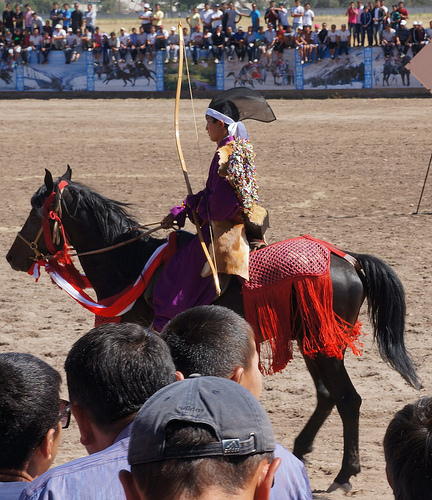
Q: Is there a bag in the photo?
A: No, there are no bags.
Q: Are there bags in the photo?
A: No, there are no bags.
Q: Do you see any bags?
A: No, there are no bags.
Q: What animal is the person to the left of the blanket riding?
A: The person is riding a horse.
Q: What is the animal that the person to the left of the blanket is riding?
A: The animal is a horse.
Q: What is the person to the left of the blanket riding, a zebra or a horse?
A: The person is riding a horse.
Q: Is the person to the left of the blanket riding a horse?
A: Yes, the person is riding a horse.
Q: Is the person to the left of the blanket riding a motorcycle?
A: No, the person is riding a horse.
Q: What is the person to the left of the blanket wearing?
A: The person is wearing a dress.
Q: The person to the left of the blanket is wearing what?
A: The person is wearing a dress.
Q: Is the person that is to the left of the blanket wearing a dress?
A: Yes, the person is wearing a dress.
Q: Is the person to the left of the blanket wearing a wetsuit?
A: No, the person is wearing a dress.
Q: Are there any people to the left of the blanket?
A: Yes, there is a person to the left of the blanket.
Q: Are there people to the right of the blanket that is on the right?
A: No, the person is to the left of the blanket.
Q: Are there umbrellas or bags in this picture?
A: No, there are no bags or umbrellas.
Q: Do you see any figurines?
A: No, there are no figurines.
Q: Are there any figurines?
A: No, there are no figurines.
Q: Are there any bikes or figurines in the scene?
A: No, there are no figurines or bikes.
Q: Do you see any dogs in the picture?
A: No, there are no dogs.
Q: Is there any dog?
A: No, there are no dogs.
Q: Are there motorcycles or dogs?
A: No, there are no dogs or motorcycles.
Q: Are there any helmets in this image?
A: No, there are no helmets.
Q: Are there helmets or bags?
A: No, there are no helmets or bags.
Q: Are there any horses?
A: Yes, there is a horse.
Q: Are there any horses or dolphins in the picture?
A: Yes, there is a horse.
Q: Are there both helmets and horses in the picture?
A: No, there is a horse but no helmets.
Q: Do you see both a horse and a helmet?
A: No, there is a horse but no helmets.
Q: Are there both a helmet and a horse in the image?
A: No, there is a horse but no helmets.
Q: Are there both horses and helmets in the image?
A: No, there is a horse but no helmets.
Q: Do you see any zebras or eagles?
A: No, there are no zebras or eagles.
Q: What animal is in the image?
A: The animal is a horse.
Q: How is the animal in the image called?
A: The animal is a horse.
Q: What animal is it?
A: The animal is a horse.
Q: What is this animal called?
A: This is a horse.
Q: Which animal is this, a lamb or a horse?
A: This is a horse.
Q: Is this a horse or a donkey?
A: This is a horse.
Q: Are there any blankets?
A: Yes, there is a blanket.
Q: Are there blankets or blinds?
A: Yes, there is a blanket.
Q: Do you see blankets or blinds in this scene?
A: Yes, there is a blanket.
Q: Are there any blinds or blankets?
A: Yes, there is a blanket.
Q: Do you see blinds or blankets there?
A: Yes, there is a blanket.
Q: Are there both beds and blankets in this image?
A: No, there is a blanket but no beds.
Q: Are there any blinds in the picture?
A: No, there are no blinds.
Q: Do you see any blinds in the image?
A: No, there are no blinds.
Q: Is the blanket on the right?
A: Yes, the blanket is on the right of the image.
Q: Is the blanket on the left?
A: No, the blanket is on the right of the image.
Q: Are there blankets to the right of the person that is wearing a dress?
A: Yes, there is a blanket to the right of the person.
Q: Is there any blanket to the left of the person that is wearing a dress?
A: No, the blanket is to the right of the person.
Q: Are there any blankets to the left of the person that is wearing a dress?
A: No, the blanket is to the right of the person.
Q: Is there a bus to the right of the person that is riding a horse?
A: No, there is a blanket to the right of the person.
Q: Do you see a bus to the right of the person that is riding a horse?
A: No, there is a blanket to the right of the person.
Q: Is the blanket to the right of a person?
A: Yes, the blanket is to the right of a person.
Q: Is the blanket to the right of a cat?
A: No, the blanket is to the right of a person.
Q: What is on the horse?
A: The blanket is on the horse.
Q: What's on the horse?
A: The blanket is on the horse.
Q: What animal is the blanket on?
A: The blanket is on the horse.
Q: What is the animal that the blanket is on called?
A: The animal is a horse.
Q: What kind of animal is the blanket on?
A: The blanket is on the horse.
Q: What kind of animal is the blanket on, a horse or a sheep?
A: The blanket is on a horse.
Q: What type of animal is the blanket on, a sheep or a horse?
A: The blanket is on a horse.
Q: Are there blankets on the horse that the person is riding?
A: Yes, there is a blanket on the horse.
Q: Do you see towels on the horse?
A: No, there is a blanket on the horse.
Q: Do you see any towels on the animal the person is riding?
A: No, there is a blanket on the horse.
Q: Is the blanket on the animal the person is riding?
A: Yes, the blanket is on the horse.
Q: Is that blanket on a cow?
A: No, the blanket is on the horse.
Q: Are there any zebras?
A: No, there are no zebras.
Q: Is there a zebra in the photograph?
A: No, there are no zebras.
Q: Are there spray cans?
A: No, there are no spray cans.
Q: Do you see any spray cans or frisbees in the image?
A: No, there are no spray cans or frisbees.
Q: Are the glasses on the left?
A: Yes, the glasses are on the left of the image.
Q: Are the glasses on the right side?
A: No, the glasses are on the left of the image.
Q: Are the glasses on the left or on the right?
A: The glasses are on the left of the image.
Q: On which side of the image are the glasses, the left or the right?
A: The glasses are on the left of the image.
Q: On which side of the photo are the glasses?
A: The glasses are on the left of the image.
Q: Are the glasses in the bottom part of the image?
A: Yes, the glasses are in the bottom of the image.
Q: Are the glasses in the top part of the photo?
A: No, the glasses are in the bottom of the image.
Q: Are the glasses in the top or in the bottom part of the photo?
A: The glasses are in the bottom of the image.